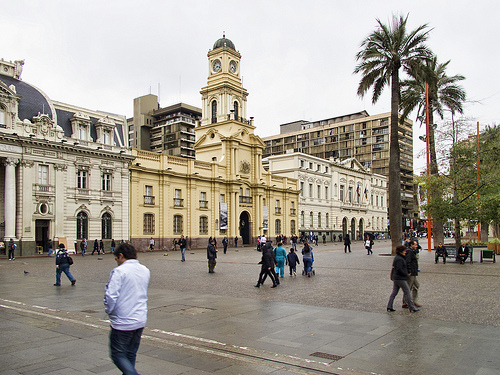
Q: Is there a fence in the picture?
A: No, there are no fences.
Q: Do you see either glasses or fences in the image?
A: No, there are no fences or glasses.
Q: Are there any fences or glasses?
A: No, there are no fences or glasses.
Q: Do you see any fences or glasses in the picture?
A: No, there are no fences or glasses.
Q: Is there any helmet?
A: No, there are no helmets.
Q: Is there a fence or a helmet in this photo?
A: No, there are no helmets or fences.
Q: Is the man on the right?
A: Yes, the man is on the right of the image.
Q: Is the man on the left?
A: No, the man is on the right of the image.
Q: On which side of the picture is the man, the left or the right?
A: The man is on the right of the image.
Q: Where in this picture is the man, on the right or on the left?
A: The man is on the right of the image.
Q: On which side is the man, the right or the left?
A: The man is on the right of the image.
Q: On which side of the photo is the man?
A: The man is on the right of the image.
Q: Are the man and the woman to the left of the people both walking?
A: Yes, both the man and the woman are walking.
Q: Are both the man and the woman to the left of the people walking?
A: Yes, both the man and the woman are walking.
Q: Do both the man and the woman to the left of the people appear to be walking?
A: Yes, both the man and the woman are walking.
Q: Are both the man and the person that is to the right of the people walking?
A: Yes, both the man and the woman are walking.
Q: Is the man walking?
A: Yes, the man is walking.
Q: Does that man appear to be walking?
A: Yes, the man is walking.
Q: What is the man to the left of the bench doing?
A: The man is walking.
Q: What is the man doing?
A: The man is walking.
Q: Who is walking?
A: The man is walking.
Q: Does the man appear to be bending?
A: No, the man is walking.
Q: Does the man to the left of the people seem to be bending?
A: No, the man is walking.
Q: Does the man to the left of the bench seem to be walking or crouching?
A: The man is walking.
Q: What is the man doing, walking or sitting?
A: The man is walking.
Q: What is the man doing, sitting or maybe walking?
A: The man is walking.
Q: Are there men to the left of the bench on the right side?
A: Yes, there is a man to the left of the bench.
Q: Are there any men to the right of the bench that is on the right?
A: No, the man is to the left of the bench.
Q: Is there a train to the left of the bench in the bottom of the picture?
A: No, there is a man to the left of the bench.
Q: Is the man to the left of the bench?
A: Yes, the man is to the left of the bench.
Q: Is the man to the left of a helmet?
A: No, the man is to the left of the bench.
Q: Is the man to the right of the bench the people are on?
A: No, the man is to the left of the bench.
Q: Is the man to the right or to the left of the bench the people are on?
A: The man is to the left of the bench.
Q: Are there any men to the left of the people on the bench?
A: Yes, there is a man to the left of the people.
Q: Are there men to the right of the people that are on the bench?
A: No, the man is to the left of the people.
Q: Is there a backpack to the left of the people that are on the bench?
A: No, there is a man to the left of the people.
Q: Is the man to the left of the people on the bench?
A: Yes, the man is to the left of the people.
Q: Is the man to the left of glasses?
A: No, the man is to the left of the people.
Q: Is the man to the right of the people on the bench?
A: No, the man is to the left of the people.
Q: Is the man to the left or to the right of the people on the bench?
A: The man is to the left of the people.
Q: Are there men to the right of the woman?
A: Yes, there is a man to the right of the woman.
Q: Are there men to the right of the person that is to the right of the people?
A: Yes, there is a man to the right of the woman.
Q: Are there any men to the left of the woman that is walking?
A: No, the man is to the right of the woman.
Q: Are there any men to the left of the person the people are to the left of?
A: No, the man is to the right of the woman.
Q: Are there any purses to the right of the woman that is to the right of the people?
A: No, there is a man to the right of the woman.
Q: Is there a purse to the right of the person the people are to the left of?
A: No, there is a man to the right of the woman.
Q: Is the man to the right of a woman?
A: Yes, the man is to the right of a woman.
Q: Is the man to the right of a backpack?
A: No, the man is to the right of a woman.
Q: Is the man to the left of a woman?
A: No, the man is to the right of a woman.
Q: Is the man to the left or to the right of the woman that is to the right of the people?
A: The man is to the right of the woman.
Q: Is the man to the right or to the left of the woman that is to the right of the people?
A: The man is to the right of the woman.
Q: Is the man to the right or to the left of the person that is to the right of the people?
A: The man is to the right of the woman.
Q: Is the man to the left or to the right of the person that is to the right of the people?
A: The man is to the right of the woman.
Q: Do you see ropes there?
A: No, there are no ropes.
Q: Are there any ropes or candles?
A: No, there are no ropes or candles.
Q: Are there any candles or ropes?
A: No, there are no ropes or candles.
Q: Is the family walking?
A: Yes, the family is walking.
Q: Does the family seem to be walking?
A: Yes, the family is walking.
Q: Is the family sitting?
A: No, the family is walking.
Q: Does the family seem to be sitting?
A: No, the family is walking.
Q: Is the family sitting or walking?
A: The family is walking.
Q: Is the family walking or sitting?
A: The family is walking.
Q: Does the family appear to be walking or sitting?
A: The family is walking.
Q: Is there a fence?
A: No, there are no fences.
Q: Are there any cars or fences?
A: No, there are no fences or cars.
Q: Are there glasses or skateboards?
A: No, there are no glasses or skateboards.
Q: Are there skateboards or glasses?
A: No, there are no glasses or skateboards.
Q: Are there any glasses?
A: No, there are no glasses.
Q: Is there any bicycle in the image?
A: No, there are no bicycles.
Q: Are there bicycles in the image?
A: No, there are no bicycles.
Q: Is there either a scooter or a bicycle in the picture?
A: No, there are no bicycles or scooters.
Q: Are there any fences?
A: No, there are no fences.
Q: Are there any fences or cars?
A: No, there are no fences or cars.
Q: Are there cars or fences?
A: No, there are no fences or cars.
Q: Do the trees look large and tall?
A: Yes, the trees are large and tall.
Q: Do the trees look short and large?
A: No, the trees are large but tall.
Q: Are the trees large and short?
A: No, the trees are large but tall.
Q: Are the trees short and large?
A: No, the trees are large but tall.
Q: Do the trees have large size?
A: Yes, the trees are large.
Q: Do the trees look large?
A: Yes, the trees are large.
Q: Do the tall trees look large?
A: Yes, the trees are large.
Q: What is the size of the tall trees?
A: The trees are large.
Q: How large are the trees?
A: The trees are large.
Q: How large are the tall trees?
A: The trees are large.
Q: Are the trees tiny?
A: No, the trees are large.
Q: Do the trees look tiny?
A: No, the trees are large.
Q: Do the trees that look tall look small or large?
A: The trees are large.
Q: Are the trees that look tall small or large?
A: The trees are large.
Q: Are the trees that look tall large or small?
A: The trees are large.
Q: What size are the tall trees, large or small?
A: The trees are large.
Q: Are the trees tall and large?
A: Yes, the trees are tall and large.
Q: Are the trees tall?
A: Yes, the trees are tall.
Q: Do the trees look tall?
A: Yes, the trees are tall.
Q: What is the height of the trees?
A: The trees are tall.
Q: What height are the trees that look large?
A: The trees are tall.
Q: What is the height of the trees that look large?
A: The trees are tall.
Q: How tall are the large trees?
A: The trees are tall.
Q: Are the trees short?
A: No, the trees are tall.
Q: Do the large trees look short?
A: No, the trees are tall.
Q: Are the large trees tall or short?
A: The trees are tall.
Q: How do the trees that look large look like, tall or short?
A: The trees are tall.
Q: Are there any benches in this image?
A: Yes, there is a bench.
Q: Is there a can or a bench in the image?
A: Yes, there is a bench.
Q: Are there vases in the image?
A: No, there are no vases.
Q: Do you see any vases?
A: No, there are no vases.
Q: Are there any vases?
A: No, there are no vases.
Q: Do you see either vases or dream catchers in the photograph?
A: No, there are no vases or dream catchers.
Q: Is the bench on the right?
A: Yes, the bench is on the right of the image.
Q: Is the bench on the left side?
A: No, the bench is on the right of the image.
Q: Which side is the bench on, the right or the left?
A: The bench is on the right of the image.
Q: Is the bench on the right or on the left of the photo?
A: The bench is on the right of the image.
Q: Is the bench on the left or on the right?
A: The bench is on the right of the image.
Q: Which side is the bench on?
A: The bench is on the right of the image.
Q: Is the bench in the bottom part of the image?
A: Yes, the bench is in the bottom of the image.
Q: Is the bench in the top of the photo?
A: No, the bench is in the bottom of the image.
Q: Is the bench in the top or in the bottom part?
A: The bench is in the bottom of the image.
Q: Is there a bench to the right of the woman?
A: Yes, there is a bench to the right of the woman.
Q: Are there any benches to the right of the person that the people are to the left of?
A: Yes, there is a bench to the right of the woman.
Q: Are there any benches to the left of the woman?
A: No, the bench is to the right of the woman.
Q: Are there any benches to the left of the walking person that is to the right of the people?
A: No, the bench is to the right of the woman.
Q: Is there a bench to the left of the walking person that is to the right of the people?
A: No, the bench is to the right of the woman.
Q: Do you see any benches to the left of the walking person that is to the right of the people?
A: No, the bench is to the right of the woman.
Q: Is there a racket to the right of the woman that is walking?
A: No, there is a bench to the right of the woman.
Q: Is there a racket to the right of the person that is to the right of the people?
A: No, there is a bench to the right of the woman.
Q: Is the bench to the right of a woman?
A: Yes, the bench is to the right of a woman.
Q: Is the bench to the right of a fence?
A: No, the bench is to the right of a woman.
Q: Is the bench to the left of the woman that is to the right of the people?
A: No, the bench is to the right of the woman.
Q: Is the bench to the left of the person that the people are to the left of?
A: No, the bench is to the right of the woman.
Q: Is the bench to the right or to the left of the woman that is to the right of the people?
A: The bench is to the right of the woman.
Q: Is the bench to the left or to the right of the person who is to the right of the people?
A: The bench is to the right of the woman.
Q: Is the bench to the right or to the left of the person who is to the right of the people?
A: The bench is to the right of the woman.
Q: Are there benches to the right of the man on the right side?
A: Yes, there is a bench to the right of the man.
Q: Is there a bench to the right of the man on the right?
A: Yes, there is a bench to the right of the man.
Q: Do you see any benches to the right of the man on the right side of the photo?
A: Yes, there is a bench to the right of the man.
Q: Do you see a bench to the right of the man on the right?
A: Yes, there is a bench to the right of the man.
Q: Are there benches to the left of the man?
A: No, the bench is to the right of the man.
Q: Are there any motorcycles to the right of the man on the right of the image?
A: No, there is a bench to the right of the man.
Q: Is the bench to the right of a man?
A: Yes, the bench is to the right of a man.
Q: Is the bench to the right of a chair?
A: No, the bench is to the right of a man.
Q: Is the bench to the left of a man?
A: No, the bench is to the right of a man.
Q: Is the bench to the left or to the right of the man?
A: The bench is to the right of the man.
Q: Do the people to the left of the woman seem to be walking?
A: Yes, the people are walking.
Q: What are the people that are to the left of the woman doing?
A: The people are walking.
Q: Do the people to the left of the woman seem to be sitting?
A: No, the people are walking.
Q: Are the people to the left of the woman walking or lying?
A: The people are walking.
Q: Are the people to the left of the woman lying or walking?
A: The people are walking.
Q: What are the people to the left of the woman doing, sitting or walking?
A: The people are walking.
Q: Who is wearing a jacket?
A: The people are wearing a jacket.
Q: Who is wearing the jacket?
A: The people are wearing a jacket.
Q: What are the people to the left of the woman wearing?
A: The people are wearing a jacket.